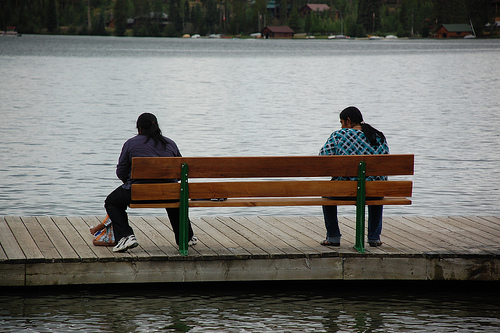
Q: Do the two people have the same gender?
A: Yes, all the people are female.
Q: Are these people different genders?
A: No, all the people are female.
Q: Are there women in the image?
A: Yes, there is a woman.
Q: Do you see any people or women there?
A: Yes, there is a woman.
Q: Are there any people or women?
A: Yes, there is a woman.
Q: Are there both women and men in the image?
A: No, there is a woman but no men.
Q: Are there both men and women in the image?
A: No, there is a woman but no men.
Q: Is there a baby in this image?
A: No, there are no babies.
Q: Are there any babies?
A: No, there are no babies.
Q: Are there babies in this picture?
A: No, there are no babies.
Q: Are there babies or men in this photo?
A: No, there are no babies or men.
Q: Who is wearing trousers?
A: The woman is wearing trousers.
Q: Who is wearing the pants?
A: The woman is wearing trousers.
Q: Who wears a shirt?
A: The woman wears a shirt.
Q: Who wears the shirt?
A: The woman wears a shirt.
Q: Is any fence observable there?
A: No, there are no fences.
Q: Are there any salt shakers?
A: No, there are no salt shakers.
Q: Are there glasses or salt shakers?
A: No, there are no salt shakers or glasses.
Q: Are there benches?
A: Yes, there is a bench.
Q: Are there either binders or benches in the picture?
A: Yes, there is a bench.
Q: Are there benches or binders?
A: Yes, there is a bench.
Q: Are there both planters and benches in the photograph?
A: No, there is a bench but no planters.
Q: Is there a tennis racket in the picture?
A: No, there are no rackets.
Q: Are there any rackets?
A: No, there are no rackets.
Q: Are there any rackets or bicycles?
A: No, there are no rackets or bicycles.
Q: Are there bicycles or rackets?
A: No, there are no rackets or bicycles.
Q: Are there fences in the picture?
A: No, there are no fences.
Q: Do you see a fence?
A: No, there are no fences.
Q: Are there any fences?
A: No, there are no fences.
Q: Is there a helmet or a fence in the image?
A: No, there are no fences or helmets.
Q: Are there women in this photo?
A: Yes, there is a woman.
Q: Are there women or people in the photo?
A: Yes, there is a woman.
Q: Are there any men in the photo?
A: No, there are no men.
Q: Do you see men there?
A: No, there are no men.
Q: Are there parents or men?
A: No, there are no men or parents.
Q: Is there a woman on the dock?
A: Yes, there is a woman on the dock.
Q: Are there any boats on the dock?
A: No, there is a woman on the dock.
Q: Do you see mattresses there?
A: No, there are no mattresses.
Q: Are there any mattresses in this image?
A: No, there are no mattresses.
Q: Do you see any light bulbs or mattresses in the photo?
A: No, there are no mattresses or light bulbs.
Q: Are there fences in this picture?
A: No, there are no fences.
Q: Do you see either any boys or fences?
A: No, there are no fences or boys.